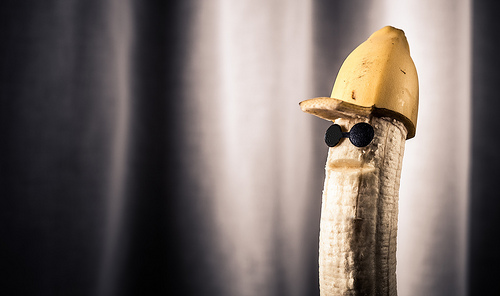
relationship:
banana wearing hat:
[308, 23, 411, 293] [315, 14, 415, 124]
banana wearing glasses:
[308, 23, 411, 293] [321, 114, 370, 149]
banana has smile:
[308, 23, 411, 293] [320, 144, 380, 182]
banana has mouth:
[308, 23, 411, 293] [320, 144, 380, 182]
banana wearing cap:
[308, 23, 411, 293] [315, 14, 415, 124]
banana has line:
[308, 23, 411, 293] [368, 178, 386, 277]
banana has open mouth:
[308, 23, 411, 293] [319, 154, 369, 174]